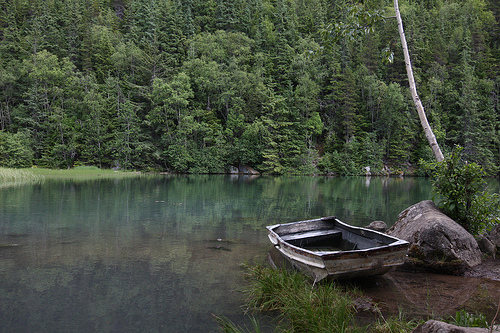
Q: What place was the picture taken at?
A: It was taken at the river.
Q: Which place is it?
A: It is a river.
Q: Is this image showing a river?
A: Yes, it is showing a river.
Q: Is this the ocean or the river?
A: It is the river.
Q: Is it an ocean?
A: No, it is a river.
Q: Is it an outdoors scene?
A: Yes, it is outdoors.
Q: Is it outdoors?
A: Yes, it is outdoors.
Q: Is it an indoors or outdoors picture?
A: It is outdoors.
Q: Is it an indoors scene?
A: No, it is outdoors.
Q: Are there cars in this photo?
A: No, there are no cars.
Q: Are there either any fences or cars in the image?
A: No, there are no cars or fences.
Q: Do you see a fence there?
A: No, there are no fences.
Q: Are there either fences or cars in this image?
A: No, there are no fences or cars.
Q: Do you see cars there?
A: No, there are no cars.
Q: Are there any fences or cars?
A: No, there are no cars or fences.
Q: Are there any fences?
A: No, there are no fences.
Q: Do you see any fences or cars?
A: No, there are no fences or cars.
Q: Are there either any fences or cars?
A: No, there are no fences or cars.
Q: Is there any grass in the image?
A: Yes, there is grass.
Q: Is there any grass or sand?
A: Yes, there is grass.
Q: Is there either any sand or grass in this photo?
A: Yes, there is grass.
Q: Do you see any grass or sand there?
A: Yes, there is grass.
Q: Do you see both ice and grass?
A: No, there is grass but no ice.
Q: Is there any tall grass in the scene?
A: Yes, there is tall grass.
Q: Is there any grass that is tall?
A: Yes, there is tall grass.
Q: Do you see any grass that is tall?
A: Yes, there is grass that is tall.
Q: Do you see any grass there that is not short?
A: Yes, there is tall grass.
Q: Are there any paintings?
A: No, there are no paintings.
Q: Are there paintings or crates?
A: No, there are no paintings or crates.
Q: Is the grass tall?
A: Yes, the grass is tall.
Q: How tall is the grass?
A: The grass is tall.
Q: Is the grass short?
A: No, the grass is tall.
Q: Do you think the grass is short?
A: No, the grass is tall.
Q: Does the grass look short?
A: No, the grass is tall.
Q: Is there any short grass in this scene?
A: No, there is grass but it is tall.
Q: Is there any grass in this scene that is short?
A: No, there is grass but it is tall.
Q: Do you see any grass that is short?
A: No, there is grass but it is tall.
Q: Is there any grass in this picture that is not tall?
A: No, there is grass but it is tall.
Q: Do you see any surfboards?
A: No, there are no surfboards.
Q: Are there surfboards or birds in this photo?
A: No, there are no surfboards or birds.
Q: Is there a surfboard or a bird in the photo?
A: No, there are no surfboards or birds.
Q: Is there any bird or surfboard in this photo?
A: No, there are no surfboards or birds.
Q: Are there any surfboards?
A: No, there are no surfboards.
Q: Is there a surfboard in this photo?
A: No, there are no surfboards.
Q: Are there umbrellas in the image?
A: No, there are no umbrellas.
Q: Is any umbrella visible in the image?
A: No, there are no umbrellas.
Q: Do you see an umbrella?
A: No, there are no umbrellas.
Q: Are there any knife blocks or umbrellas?
A: No, there are no umbrellas or knife blocks.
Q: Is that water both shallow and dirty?
A: Yes, the water is shallow and dirty.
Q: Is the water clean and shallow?
A: No, the water is shallow but dirty.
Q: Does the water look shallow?
A: Yes, the water is shallow.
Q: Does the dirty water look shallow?
A: Yes, the water is shallow.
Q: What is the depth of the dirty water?
A: The water is shallow.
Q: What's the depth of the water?
A: The water is shallow.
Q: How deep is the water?
A: The water is shallow.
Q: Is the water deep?
A: No, the water is shallow.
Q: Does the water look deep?
A: No, the water is shallow.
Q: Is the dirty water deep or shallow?
A: The water is shallow.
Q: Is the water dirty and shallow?
A: Yes, the water is dirty and shallow.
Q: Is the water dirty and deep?
A: No, the water is dirty but shallow.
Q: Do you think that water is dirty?
A: Yes, the water is dirty.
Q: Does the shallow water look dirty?
A: Yes, the water is dirty.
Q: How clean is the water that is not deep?
A: The water is dirty.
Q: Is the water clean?
A: No, the water is dirty.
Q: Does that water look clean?
A: No, the water is dirty.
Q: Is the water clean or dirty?
A: The water is dirty.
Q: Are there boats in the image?
A: Yes, there is a boat.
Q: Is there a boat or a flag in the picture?
A: Yes, there is a boat.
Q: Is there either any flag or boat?
A: Yes, there is a boat.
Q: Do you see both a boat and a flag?
A: No, there is a boat but no flags.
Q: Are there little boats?
A: Yes, there is a little boat.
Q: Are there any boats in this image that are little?
A: Yes, there is a boat that is little.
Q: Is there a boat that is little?
A: Yes, there is a boat that is little.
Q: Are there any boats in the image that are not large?
A: Yes, there is a little boat.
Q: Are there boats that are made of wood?
A: Yes, there is a boat that is made of wood.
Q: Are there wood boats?
A: Yes, there is a boat that is made of wood.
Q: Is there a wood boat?
A: Yes, there is a boat that is made of wood.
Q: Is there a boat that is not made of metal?
A: Yes, there is a boat that is made of wood.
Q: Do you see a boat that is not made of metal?
A: Yes, there is a boat that is made of wood.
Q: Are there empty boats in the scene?
A: Yes, there is an empty boat.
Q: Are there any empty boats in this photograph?
A: Yes, there is an empty boat.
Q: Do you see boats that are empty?
A: Yes, there is a boat that is empty.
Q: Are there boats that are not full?
A: Yes, there is a empty boat.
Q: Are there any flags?
A: No, there are no flags.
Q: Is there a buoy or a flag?
A: No, there are no flags or buoys.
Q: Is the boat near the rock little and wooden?
A: Yes, the boat is little and wooden.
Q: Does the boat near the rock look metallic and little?
A: No, the boat is little but wooden.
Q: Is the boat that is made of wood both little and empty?
A: Yes, the boat is little and empty.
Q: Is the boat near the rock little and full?
A: No, the boat is little but empty.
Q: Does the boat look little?
A: Yes, the boat is little.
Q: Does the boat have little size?
A: Yes, the boat is little.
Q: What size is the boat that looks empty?
A: The boat is little.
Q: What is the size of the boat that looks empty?
A: The boat is little.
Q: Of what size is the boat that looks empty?
A: The boat is little.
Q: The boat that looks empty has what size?
A: The boat is little.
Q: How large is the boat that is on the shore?
A: The boat is little.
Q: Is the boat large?
A: No, the boat is little.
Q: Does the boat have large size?
A: No, the boat is little.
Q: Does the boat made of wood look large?
A: No, the boat is little.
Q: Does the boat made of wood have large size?
A: No, the boat is little.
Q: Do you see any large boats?
A: No, there is a boat but it is little.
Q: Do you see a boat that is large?
A: No, there is a boat but it is little.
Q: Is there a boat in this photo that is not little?
A: No, there is a boat but it is little.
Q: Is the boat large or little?
A: The boat is little.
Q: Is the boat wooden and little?
A: Yes, the boat is wooden and little.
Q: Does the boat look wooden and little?
A: Yes, the boat is wooden and little.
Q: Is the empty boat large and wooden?
A: No, the boat is wooden but little.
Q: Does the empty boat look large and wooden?
A: No, the boat is wooden but little.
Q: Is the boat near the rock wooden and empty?
A: Yes, the boat is wooden and empty.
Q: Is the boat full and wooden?
A: No, the boat is wooden but empty.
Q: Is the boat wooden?
A: Yes, the boat is wooden.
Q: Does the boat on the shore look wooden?
A: Yes, the boat is wooden.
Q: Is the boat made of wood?
A: Yes, the boat is made of wood.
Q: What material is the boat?
A: The boat is made of wood.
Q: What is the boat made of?
A: The boat is made of wood.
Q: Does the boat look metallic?
A: No, the boat is wooden.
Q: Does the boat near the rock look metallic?
A: No, the boat is wooden.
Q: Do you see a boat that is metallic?
A: No, there is a boat but it is wooden.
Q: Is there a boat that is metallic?
A: No, there is a boat but it is wooden.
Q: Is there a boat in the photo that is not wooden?
A: No, there is a boat but it is wooden.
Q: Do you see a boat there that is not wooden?
A: No, there is a boat but it is wooden.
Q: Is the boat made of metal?
A: No, the boat is made of wood.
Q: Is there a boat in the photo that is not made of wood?
A: No, there is a boat but it is made of wood.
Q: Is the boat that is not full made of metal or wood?
A: The boat is made of wood.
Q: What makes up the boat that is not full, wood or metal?
A: The boat is made of wood.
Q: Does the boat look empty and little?
A: Yes, the boat is empty and little.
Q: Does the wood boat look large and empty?
A: No, the boat is empty but little.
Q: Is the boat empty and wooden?
A: Yes, the boat is empty and wooden.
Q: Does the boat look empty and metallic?
A: No, the boat is empty but wooden.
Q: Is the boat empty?
A: Yes, the boat is empty.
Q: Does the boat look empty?
A: Yes, the boat is empty.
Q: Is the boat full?
A: No, the boat is empty.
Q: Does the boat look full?
A: No, the boat is empty.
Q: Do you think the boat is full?
A: No, the boat is empty.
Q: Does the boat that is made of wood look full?
A: No, the boat is empty.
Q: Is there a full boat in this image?
A: No, there is a boat but it is empty.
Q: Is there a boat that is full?
A: No, there is a boat but it is empty.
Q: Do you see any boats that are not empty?
A: No, there is a boat but it is empty.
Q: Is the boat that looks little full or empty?
A: The boat is empty.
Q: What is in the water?
A: The boat is in the water.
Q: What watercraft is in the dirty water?
A: The watercraft is a boat.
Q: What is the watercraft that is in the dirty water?
A: The watercraft is a boat.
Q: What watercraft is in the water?
A: The watercraft is a boat.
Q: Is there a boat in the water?
A: Yes, there is a boat in the water.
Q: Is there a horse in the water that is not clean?
A: No, there is a boat in the water.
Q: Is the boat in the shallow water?
A: Yes, the boat is in the water.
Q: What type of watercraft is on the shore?
A: The watercraft is a boat.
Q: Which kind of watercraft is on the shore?
A: The watercraft is a boat.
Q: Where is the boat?
A: The boat is on the sea shore.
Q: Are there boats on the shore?
A: Yes, there is a boat on the shore.